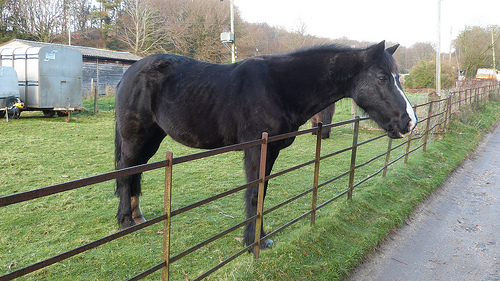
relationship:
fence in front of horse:
[2, 80, 496, 277] [112, 38, 415, 251]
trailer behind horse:
[0, 47, 86, 122] [92, 23, 446, 250]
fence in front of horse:
[2, 80, 496, 277] [117, 45, 419, 150]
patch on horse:
[389, 72, 424, 134] [87, 28, 427, 240]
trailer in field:
[3, 42, 85, 117] [3, 93, 466, 279]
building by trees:
[0, 37, 145, 97] [2, 0, 230, 57]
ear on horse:
[385, 42, 400, 54] [112, 38, 415, 251]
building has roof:
[56, 36, 141, 128] [74, 44, 143, 63]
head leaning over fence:
[358, 37, 418, 139] [2, 80, 496, 277]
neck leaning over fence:
[268, 43, 358, 125] [2, 80, 496, 277]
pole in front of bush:
[435, 0, 445, 99] [400, 56, 457, 91]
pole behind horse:
[227, 0, 240, 63] [112, 38, 415, 251]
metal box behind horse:
[217, 29, 232, 44] [112, 38, 415, 251]